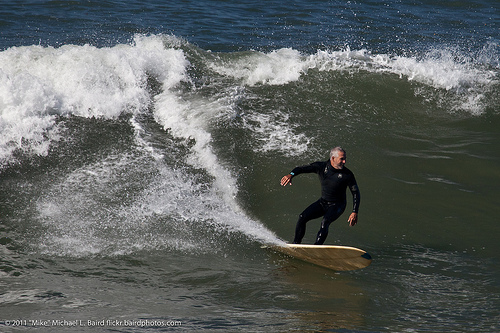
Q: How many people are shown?
A: 1.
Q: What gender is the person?
A: Male.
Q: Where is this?
A: Ocean.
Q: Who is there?
A: Surfer.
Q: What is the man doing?
A: Surfing.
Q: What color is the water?
A: Green.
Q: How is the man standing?
A: Legs bent.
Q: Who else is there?
A: No one.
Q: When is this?
A: Afternoon.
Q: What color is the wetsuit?
A: Black.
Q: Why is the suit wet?
A: It is in the water.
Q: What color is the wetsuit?
A: Black.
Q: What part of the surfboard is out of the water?
A: Front.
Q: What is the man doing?
A: Surfing.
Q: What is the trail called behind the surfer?
A: Wake.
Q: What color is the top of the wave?
A: White.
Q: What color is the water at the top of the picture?
A: Blue.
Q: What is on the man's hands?
A: Nothing.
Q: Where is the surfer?
A: Ocean.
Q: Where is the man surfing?
A: In the ocean.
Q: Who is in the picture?
A: A man.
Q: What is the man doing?
A: Surfing.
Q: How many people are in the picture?
A: 1.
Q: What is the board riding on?
A: A wave.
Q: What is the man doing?
A: Surfing.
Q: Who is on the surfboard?
A: A surfer.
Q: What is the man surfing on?
A: A wave.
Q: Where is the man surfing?
A: The ocean.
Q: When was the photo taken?
A: Daytime.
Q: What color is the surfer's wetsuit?
A: Black.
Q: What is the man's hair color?
A: White.